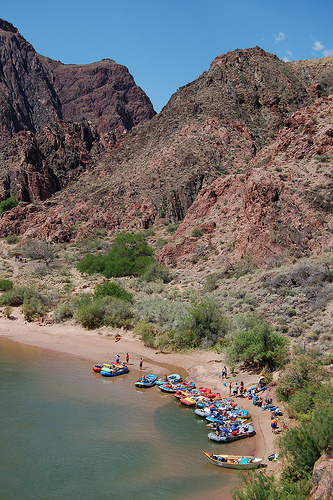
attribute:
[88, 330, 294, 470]
rafters — group, colorful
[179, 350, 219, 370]
sand — brown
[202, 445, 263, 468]
boat — small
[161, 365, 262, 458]
rafts — blue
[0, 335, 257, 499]
water — shallow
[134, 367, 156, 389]
boat — blue, gray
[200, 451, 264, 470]
boat — tan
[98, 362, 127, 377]
boat — blue and yellow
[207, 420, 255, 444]
boat — gray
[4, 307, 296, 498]
shore — sandy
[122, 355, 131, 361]
shirt — red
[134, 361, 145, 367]
pants — dark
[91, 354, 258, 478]
rafts — beached, colorful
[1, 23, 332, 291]
hills — big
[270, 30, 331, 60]
clouds — white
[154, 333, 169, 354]
tree — short, growing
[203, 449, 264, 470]
boat — red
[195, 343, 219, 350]
grass — green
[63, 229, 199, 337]
trees — thrive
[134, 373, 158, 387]
boat — in water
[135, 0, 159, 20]
boat — in the water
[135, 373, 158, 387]
raft — inflatable, blue, red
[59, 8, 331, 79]
sky — blue